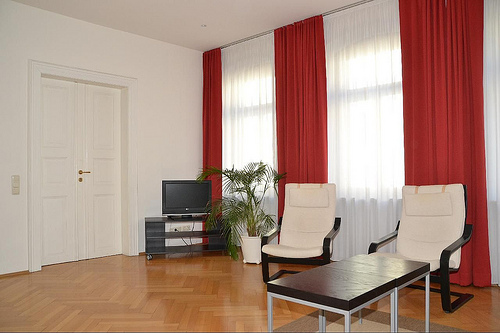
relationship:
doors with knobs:
[17, 65, 154, 238] [61, 147, 127, 188]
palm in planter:
[194, 153, 286, 261] [238, 235, 263, 265]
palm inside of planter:
[194, 153, 286, 261] [238, 235, 263, 263]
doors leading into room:
[33, 62, 155, 274] [7, 11, 489, 331]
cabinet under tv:
[144, 215, 233, 260] [161, 178, 212, 218]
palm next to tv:
[207, 153, 272, 227] [147, 150, 215, 240]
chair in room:
[370, 179, 477, 313] [167, 42, 477, 301]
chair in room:
[262, 170, 350, 288] [167, 42, 477, 301]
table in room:
[253, 253, 438, 320] [43, 52, 480, 326]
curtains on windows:
[221, 29, 278, 209] [206, 57, 494, 252]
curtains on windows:
[219, 0, 499, 285] [206, 57, 494, 252]